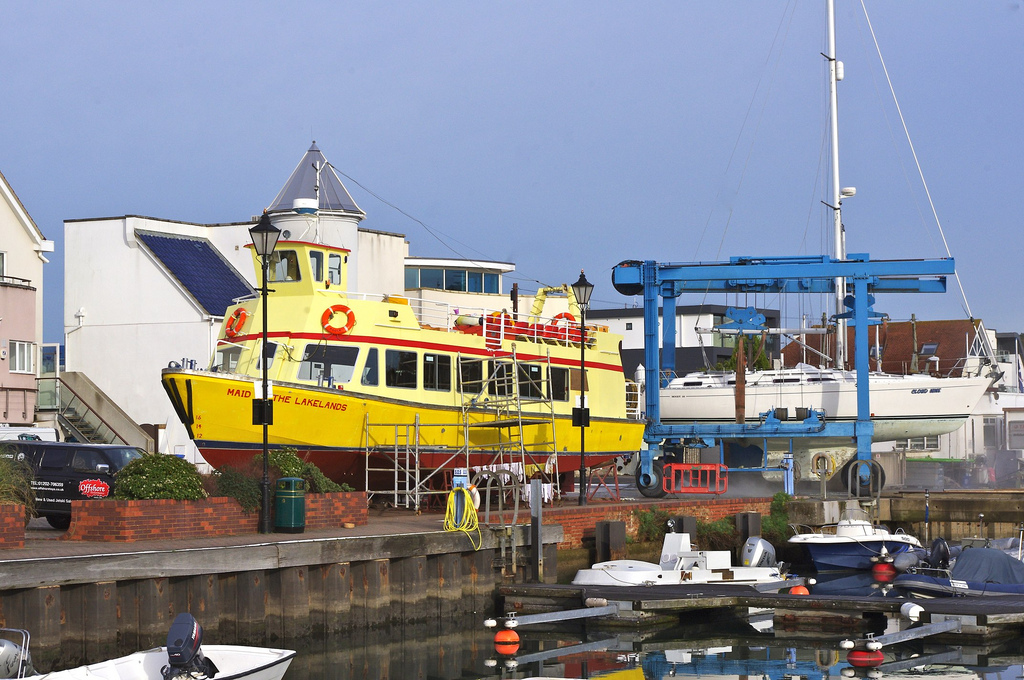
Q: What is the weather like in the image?
A: It is clear.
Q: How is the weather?
A: It is clear.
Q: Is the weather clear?
A: Yes, it is clear.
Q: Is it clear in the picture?
A: Yes, it is clear.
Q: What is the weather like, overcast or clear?
A: It is clear.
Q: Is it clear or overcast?
A: It is clear.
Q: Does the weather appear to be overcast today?
A: No, it is clear.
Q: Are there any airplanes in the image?
A: No, there are no airplanes.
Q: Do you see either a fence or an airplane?
A: No, there are no airplanes or fences.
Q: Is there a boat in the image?
A: Yes, there is a boat.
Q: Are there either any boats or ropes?
A: Yes, there is a boat.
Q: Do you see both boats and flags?
A: No, there is a boat but no flags.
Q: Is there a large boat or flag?
A: Yes, there is a large boat.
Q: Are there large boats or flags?
A: Yes, there is a large boat.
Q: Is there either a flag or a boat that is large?
A: Yes, the boat is large.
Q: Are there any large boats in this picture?
A: Yes, there is a large boat.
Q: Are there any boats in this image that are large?
A: Yes, there is a boat that is large.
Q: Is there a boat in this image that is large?
A: Yes, there is a boat that is large.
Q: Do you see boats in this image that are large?
A: Yes, there is a boat that is large.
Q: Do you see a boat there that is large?
A: Yes, there is a boat that is large.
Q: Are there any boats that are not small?
A: Yes, there is a large boat.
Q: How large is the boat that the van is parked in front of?
A: The boat is large.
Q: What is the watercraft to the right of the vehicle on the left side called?
A: The watercraft is a boat.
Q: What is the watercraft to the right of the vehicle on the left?
A: The watercraft is a boat.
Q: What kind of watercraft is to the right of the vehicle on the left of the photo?
A: The watercraft is a boat.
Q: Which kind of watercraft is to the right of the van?
A: The watercraft is a boat.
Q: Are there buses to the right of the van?
A: No, there is a boat to the right of the van.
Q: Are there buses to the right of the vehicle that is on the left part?
A: No, there is a boat to the right of the van.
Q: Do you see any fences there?
A: No, there are no fences.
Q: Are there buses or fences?
A: No, there are no fences or buses.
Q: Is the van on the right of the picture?
A: No, the van is on the left of the image.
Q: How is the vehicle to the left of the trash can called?
A: The vehicle is a van.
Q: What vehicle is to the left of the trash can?
A: The vehicle is a van.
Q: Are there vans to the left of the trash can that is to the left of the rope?
A: Yes, there is a van to the left of the trash can.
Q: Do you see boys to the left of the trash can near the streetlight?
A: No, there is a van to the left of the garbage bin.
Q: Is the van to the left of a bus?
A: No, the van is to the left of the garbage can.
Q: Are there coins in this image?
A: No, there are no coins.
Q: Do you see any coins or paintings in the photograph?
A: No, there are no coins or paintings.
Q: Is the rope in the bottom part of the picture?
A: Yes, the rope is in the bottom of the image.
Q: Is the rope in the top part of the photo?
A: No, the rope is in the bottom of the image.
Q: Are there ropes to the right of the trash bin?
A: Yes, there is a rope to the right of the trash bin.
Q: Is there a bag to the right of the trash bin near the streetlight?
A: No, there is a rope to the right of the trash bin.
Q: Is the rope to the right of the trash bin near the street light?
A: Yes, the rope is to the right of the garbage can.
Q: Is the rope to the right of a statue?
A: No, the rope is to the right of the garbage can.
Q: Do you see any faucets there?
A: No, there are no faucets.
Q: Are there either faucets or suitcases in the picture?
A: No, there are no faucets or suitcases.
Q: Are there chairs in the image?
A: No, there are no chairs.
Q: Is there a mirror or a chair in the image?
A: No, there are no chairs or mirrors.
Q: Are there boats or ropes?
A: Yes, there is a boat.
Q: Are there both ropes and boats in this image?
A: Yes, there are both a boat and a rope.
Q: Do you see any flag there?
A: No, there are no flags.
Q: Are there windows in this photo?
A: Yes, there is a window.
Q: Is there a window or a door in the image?
A: Yes, there is a window.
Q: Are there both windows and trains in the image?
A: No, there is a window but no trains.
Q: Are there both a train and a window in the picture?
A: No, there is a window but no trains.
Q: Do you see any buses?
A: No, there are no buses.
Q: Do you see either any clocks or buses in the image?
A: No, there are no buses or clocks.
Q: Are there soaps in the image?
A: No, there are no soaps.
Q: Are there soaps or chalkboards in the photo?
A: No, there are no soaps or chalkboards.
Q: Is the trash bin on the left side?
A: Yes, the trash bin is on the left of the image.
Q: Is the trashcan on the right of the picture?
A: No, the trashcan is on the left of the image.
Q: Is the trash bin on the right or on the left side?
A: The trash bin is on the left of the image.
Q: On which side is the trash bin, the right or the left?
A: The trash bin is on the left of the image.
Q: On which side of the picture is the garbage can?
A: The garbage can is on the left of the image.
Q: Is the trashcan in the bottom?
A: Yes, the trashcan is in the bottom of the image.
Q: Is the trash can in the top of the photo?
A: No, the trash can is in the bottom of the image.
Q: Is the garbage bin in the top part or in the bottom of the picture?
A: The garbage bin is in the bottom of the image.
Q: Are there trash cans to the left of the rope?
A: Yes, there is a trash can to the left of the rope.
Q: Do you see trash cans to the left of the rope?
A: Yes, there is a trash can to the left of the rope.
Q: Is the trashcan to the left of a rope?
A: Yes, the trashcan is to the left of a rope.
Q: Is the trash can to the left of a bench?
A: No, the trash can is to the left of a rope.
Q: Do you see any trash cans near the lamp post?
A: Yes, there is a trash can near the lamp post.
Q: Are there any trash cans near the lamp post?
A: Yes, there is a trash can near the lamp post.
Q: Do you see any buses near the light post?
A: No, there is a trash can near the light post.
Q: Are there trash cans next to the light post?
A: Yes, there is a trash can next to the light post.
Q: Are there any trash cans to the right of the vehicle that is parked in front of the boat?
A: Yes, there is a trash can to the right of the van.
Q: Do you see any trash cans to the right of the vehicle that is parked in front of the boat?
A: Yes, there is a trash can to the right of the van.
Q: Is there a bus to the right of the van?
A: No, there is a trash can to the right of the van.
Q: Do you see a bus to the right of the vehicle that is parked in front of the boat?
A: No, there is a trash can to the right of the van.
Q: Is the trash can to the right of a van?
A: Yes, the trash can is to the right of a van.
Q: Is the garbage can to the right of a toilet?
A: No, the garbage can is to the right of a van.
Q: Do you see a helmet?
A: No, there are no helmets.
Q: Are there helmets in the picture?
A: No, there are no helmets.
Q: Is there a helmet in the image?
A: No, there are no helmets.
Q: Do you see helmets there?
A: No, there are no helmets.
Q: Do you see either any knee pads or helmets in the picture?
A: No, there are no helmets or knee pads.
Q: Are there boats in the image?
A: Yes, there is a boat.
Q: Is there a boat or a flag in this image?
A: Yes, there is a boat.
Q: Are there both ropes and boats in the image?
A: Yes, there are both a boat and a rope.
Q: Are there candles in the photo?
A: No, there are no candles.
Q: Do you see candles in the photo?
A: No, there are no candles.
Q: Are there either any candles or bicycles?
A: No, there are no candles or bicycles.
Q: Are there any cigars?
A: No, there are no cigars.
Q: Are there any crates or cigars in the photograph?
A: No, there are no cigars or crates.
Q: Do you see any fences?
A: No, there are no fences.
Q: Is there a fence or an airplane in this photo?
A: No, there are no fences or airplanes.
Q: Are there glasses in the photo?
A: No, there are no glasses.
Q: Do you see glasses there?
A: No, there are no glasses.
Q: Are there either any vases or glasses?
A: No, there are no glasses or vases.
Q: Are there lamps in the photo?
A: Yes, there is a lamp.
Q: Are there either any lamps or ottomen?
A: Yes, there is a lamp.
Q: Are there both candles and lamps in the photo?
A: No, there is a lamp but no candles.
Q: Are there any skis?
A: No, there are no skis.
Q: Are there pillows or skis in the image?
A: No, there are no skis or pillows.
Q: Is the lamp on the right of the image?
A: No, the lamp is on the left of the image.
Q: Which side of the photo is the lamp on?
A: The lamp is on the left of the image.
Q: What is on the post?
A: The lamp is on the post.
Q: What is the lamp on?
A: The lamp is on the post.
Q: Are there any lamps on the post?
A: Yes, there is a lamp on the post.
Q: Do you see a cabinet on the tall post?
A: No, there is a lamp on the post.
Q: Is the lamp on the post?
A: Yes, the lamp is on the post.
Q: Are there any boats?
A: Yes, there is a boat.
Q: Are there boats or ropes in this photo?
A: Yes, there is a boat.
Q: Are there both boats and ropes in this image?
A: Yes, there are both a boat and a rope.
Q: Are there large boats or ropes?
A: Yes, there is a large boat.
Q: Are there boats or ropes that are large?
A: Yes, the boat is large.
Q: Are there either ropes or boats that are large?
A: Yes, the boat is large.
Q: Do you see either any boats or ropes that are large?
A: Yes, the boat is large.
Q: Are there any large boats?
A: Yes, there is a large boat.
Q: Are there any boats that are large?
A: Yes, there is a boat that is large.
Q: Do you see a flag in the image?
A: No, there are no flags.